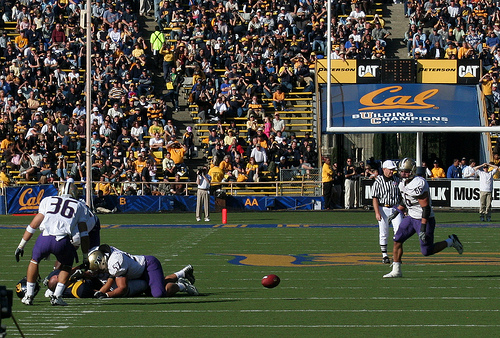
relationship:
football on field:
[248, 261, 294, 293] [227, 226, 393, 327]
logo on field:
[231, 246, 351, 282] [227, 226, 393, 327]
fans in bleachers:
[152, 71, 278, 138] [55, 71, 332, 207]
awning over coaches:
[214, 162, 266, 182] [130, 109, 300, 184]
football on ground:
[248, 261, 294, 293] [208, 241, 339, 332]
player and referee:
[378, 161, 445, 292] [368, 158, 401, 261]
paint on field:
[217, 247, 285, 286] [227, 226, 393, 327]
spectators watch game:
[138, 42, 259, 134] [9, 131, 446, 331]